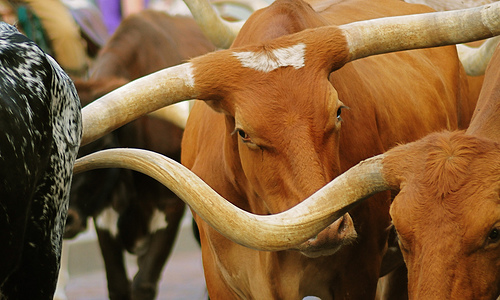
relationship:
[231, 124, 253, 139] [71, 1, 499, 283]
eye of cow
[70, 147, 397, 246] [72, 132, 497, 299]
horn on cow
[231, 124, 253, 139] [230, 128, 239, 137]
eye with lashes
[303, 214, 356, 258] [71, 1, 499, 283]
nose of cow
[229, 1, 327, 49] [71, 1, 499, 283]
bump on cow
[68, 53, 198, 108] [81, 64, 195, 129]
edge of a horn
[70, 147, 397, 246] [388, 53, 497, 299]
horn of bull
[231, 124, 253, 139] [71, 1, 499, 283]
eye of bull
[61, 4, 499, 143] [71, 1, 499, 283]
horns of cow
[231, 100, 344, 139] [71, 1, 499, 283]
eyes of cow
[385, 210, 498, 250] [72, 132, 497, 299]
eyes of cow